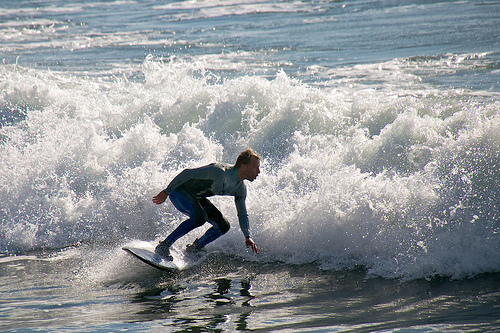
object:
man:
[152, 149, 262, 261]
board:
[122, 246, 178, 271]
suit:
[166, 163, 253, 249]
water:
[0, 1, 500, 332]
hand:
[246, 237, 259, 254]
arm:
[167, 165, 222, 193]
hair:
[235, 148, 261, 167]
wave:
[1, 57, 500, 283]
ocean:
[0, 0, 500, 332]